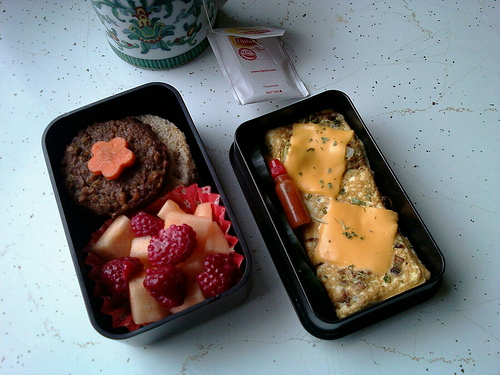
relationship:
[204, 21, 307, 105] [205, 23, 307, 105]
tea in a bag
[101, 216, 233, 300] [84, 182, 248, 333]
berries are in cupcake tin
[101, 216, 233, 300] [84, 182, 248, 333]
berries are in a cupcake tin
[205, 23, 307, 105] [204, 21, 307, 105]
bag has tea